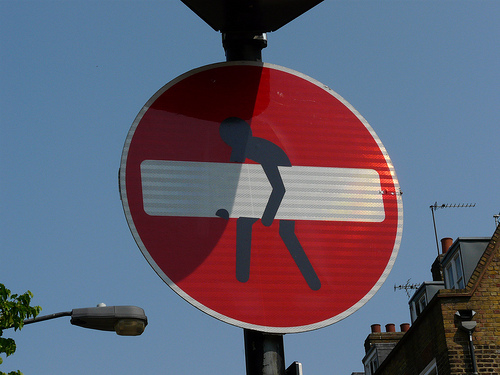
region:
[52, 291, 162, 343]
horizontal grey street light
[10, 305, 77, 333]
pole holding street light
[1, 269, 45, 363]
tree leaves in front of pole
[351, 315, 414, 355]
chimney on roof top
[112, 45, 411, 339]
sign with figure of human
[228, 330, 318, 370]
metal pole for sign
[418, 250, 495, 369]
building made of brick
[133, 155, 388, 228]
white rectangle on sign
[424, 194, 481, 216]
television antenna on roof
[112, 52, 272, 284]
shadow on round red sign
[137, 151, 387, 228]
Large white rectangular shape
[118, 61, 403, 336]
Red circle with gray trim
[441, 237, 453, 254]
brown chimney on top of building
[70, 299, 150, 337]
gray street light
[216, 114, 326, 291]
Gray person bent over holding something white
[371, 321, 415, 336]
Three brown chimneys in a row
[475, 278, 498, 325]
Light colored bricks on side of building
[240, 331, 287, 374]
metal pole holding sign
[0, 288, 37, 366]
Green leaves by light pole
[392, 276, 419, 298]
Metal antenna coming off building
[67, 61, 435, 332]
Red sign with white stripe.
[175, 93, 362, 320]
Black character holding white stripe.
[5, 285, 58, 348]
Green trees against the sky.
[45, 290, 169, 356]
Gray light against sky.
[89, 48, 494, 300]
Red sign on pole.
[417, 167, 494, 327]
Buildings in the background.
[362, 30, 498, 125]
Blue sky with no clouds.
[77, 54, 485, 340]
Red circle sign.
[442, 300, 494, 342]
Brick on the building.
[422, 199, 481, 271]
Smoke stacks on building.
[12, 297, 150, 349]
Street light that is currently off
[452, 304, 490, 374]
Drain pipe on side of building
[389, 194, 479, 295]
Antennas on the roof tops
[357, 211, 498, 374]
Brick building in the background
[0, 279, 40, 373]
Tree branches near street light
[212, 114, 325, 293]
Sticker of man on red sign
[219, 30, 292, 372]
Pole the red sign is on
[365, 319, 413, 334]
Three chimneys next to each other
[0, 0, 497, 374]
Open sky shown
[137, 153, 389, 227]
White bar on the sign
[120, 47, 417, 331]
red and white circular sign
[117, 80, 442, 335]
man carrying surfboard sign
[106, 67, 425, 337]
circle sign on pole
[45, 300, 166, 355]
light coming from pole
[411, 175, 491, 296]
antenna on top of building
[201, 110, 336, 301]
graphic art on red circle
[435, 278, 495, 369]
brick building in corner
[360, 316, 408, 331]
three round containers on top of building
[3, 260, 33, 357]
green leaves in corner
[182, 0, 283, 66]
top of light on sign